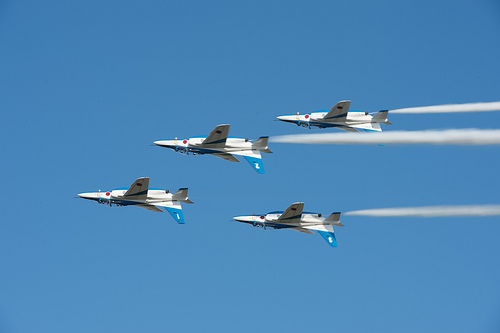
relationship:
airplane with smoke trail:
[230, 202, 345, 249] [341, 203, 499, 219]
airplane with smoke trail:
[152, 122, 274, 175] [268, 127, 500, 146]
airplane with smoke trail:
[275, 98, 393, 133] [367, 100, 499, 116]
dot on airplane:
[104, 190, 112, 197] [76, 176, 195, 225]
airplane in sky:
[150, 124, 275, 175] [1, 0, 499, 332]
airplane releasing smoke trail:
[275, 98, 393, 133] [367, 100, 499, 116]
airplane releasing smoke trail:
[152, 122, 274, 175] [268, 127, 500, 146]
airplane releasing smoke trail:
[230, 202, 345, 249] [341, 203, 499, 219]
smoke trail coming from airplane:
[341, 203, 499, 219] [230, 202, 345, 249]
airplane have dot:
[150, 124, 275, 175] [104, 190, 112, 197]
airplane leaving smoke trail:
[150, 124, 275, 175] [341, 203, 499, 219]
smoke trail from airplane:
[341, 203, 499, 219] [230, 202, 345, 249]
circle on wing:
[135, 181, 143, 189] [121, 175, 151, 197]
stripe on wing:
[123, 189, 148, 197] [121, 175, 151, 197]